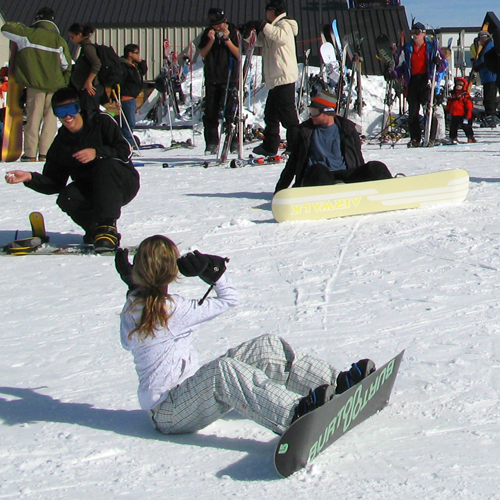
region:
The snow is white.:
[311, 247, 456, 315]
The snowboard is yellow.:
[282, 183, 464, 213]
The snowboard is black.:
[268, 402, 367, 463]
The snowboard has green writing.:
[288, 333, 413, 470]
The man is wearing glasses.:
[45, 98, 91, 132]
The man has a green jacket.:
[19, 27, 70, 94]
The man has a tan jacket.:
[260, 30, 302, 83]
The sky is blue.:
[412, 4, 459, 26]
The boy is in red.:
[441, 74, 478, 131]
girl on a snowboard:
[114, 234, 401, 476]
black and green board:
[272, 346, 403, 476]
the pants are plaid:
[150, 336, 336, 433]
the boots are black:
[294, 360, 371, 411]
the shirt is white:
[122, 273, 233, 411]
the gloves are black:
[115, 246, 226, 285]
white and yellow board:
[274, 169, 469, 222]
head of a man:
[51, 89, 81, 127]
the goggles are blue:
[52, 104, 78, 119]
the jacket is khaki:
[264, 11, 299, 88]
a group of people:
[13, 9, 494, 476]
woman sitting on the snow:
[106, 223, 391, 471]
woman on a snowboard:
[103, 213, 408, 487]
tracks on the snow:
[263, 231, 446, 337]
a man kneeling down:
[16, 77, 153, 247]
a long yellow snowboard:
[260, 168, 479, 223]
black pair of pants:
[48, 151, 142, 231]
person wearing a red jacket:
[443, 72, 475, 130]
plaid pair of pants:
[154, 331, 331, 442]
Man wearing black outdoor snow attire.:
[6, 81, 147, 264]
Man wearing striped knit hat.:
[257, 74, 384, 167]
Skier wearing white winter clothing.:
[88, 234, 382, 445]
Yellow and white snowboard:
[258, 131, 490, 225]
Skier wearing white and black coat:
[235, 0, 312, 171]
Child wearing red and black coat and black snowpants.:
[440, 54, 486, 156]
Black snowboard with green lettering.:
[248, 332, 435, 485]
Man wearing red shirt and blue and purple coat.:
[376, 9, 454, 115]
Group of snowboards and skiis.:
[294, 2, 383, 134]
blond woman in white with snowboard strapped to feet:
[95, 224, 408, 476]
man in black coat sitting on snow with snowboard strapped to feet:
[277, 92, 474, 226]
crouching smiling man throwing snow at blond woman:
[7, 89, 138, 248]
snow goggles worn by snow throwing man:
[52, 104, 80, 117]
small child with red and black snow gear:
[445, 77, 473, 140]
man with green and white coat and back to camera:
[0, 7, 74, 159]